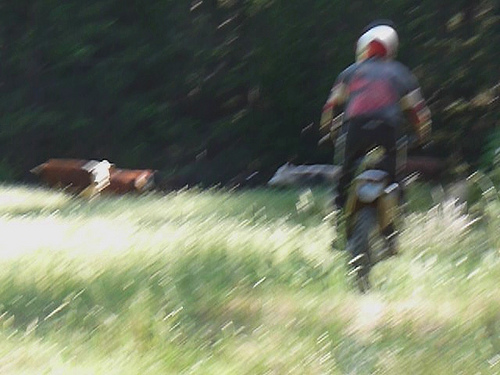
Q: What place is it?
A: It is a field.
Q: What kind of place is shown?
A: It is a field.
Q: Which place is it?
A: It is a field.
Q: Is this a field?
A: Yes, it is a field.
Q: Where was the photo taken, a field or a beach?
A: It was taken at a field.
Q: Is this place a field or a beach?
A: It is a field.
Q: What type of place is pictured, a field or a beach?
A: It is a field.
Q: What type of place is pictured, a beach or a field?
A: It is a field.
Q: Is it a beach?
A: No, it is a field.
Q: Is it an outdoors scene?
A: Yes, it is outdoors.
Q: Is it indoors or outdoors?
A: It is outdoors.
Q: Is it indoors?
A: No, it is outdoors.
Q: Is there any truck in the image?
A: Yes, there is a truck.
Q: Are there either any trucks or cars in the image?
A: Yes, there is a truck.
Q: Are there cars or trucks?
A: Yes, there is a truck.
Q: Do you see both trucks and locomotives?
A: No, there is a truck but no locomotives.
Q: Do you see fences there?
A: No, there are no fences.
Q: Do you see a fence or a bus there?
A: No, there are no fences or buses.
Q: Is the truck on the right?
A: No, the truck is on the left of the image.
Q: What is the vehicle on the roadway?
A: The vehicle is a truck.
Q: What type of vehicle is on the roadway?
A: The vehicle is a truck.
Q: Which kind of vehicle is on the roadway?
A: The vehicle is a truck.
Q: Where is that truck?
A: The truck is on the roadway.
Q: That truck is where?
A: The truck is on the roadway.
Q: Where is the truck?
A: The truck is on the roadway.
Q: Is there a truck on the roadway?
A: Yes, there is a truck on the roadway.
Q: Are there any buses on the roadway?
A: No, there is a truck on the roadway.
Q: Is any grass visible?
A: Yes, there is grass.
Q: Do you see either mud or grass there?
A: Yes, there is grass.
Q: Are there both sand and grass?
A: No, there is grass but no sand.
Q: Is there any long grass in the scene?
A: Yes, there is long grass.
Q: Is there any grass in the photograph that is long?
A: Yes, there is grass that is long.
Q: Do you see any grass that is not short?
A: Yes, there is long grass.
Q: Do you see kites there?
A: No, there are no kites.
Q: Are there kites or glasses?
A: No, there are no kites or glasses.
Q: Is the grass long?
A: Yes, the grass is long.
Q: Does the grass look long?
A: Yes, the grass is long.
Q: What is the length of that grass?
A: The grass is long.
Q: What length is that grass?
A: The grass is long.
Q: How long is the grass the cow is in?
A: The grass is long.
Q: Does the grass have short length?
A: No, the grass is long.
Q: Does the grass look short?
A: No, the grass is long.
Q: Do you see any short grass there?
A: No, there is grass but it is long.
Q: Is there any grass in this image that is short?
A: No, there is grass but it is long.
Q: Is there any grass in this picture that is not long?
A: No, there is grass but it is long.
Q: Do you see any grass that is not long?
A: No, there is grass but it is long.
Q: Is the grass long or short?
A: The grass is long.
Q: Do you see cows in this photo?
A: Yes, there is a cow.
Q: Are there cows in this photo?
A: Yes, there is a cow.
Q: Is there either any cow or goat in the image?
A: Yes, there is a cow.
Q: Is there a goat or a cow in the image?
A: Yes, there is a cow.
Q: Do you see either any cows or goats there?
A: Yes, there is a cow.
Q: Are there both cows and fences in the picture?
A: No, there is a cow but no fences.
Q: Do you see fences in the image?
A: No, there are no fences.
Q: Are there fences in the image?
A: No, there are no fences.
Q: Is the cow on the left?
A: Yes, the cow is on the left of the image.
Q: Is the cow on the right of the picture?
A: No, the cow is on the left of the image.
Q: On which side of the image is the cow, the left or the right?
A: The cow is on the left of the image.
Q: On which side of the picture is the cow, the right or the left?
A: The cow is on the left of the image.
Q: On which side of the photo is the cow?
A: The cow is on the left of the image.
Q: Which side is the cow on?
A: The cow is on the left of the image.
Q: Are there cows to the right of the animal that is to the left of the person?
A: No, the cow is to the left of the animal.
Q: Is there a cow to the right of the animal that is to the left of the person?
A: No, the cow is to the left of the animal.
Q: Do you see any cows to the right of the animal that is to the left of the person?
A: No, the cow is to the left of the animal.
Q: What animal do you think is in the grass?
A: The animal is a cow.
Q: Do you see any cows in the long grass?
A: Yes, there is a cow in the grass.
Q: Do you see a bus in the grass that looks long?
A: No, there is a cow in the grass.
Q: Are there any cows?
A: Yes, there is a cow.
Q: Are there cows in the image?
A: Yes, there is a cow.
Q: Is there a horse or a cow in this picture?
A: Yes, there is a cow.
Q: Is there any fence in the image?
A: No, there are no fences.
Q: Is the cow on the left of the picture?
A: Yes, the cow is on the left of the image.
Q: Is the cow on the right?
A: No, the cow is on the left of the image.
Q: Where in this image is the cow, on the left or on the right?
A: The cow is on the left of the image.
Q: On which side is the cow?
A: The cow is on the left of the image.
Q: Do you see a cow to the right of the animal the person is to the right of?
A: No, the cow is to the left of the animal.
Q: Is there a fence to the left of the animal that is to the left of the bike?
A: No, there is a cow to the left of the animal.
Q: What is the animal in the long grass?
A: The animal is a cow.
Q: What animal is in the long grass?
A: The animal is a cow.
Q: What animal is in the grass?
A: The animal is a cow.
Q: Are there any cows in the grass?
A: Yes, there is a cow in the grass.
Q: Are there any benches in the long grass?
A: No, there is a cow in the grass.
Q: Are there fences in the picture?
A: No, there are no fences.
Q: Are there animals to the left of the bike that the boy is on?
A: Yes, there is an animal to the left of the bike.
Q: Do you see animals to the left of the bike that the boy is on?
A: Yes, there is an animal to the left of the bike.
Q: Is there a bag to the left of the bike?
A: No, there is an animal to the left of the bike.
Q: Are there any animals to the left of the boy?
A: Yes, there is an animal to the left of the boy.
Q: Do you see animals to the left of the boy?
A: Yes, there is an animal to the left of the boy.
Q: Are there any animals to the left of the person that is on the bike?
A: Yes, there is an animal to the left of the boy.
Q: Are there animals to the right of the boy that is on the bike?
A: No, the animal is to the left of the boy.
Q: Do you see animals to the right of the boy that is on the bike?
A: No, the animal is to the left of the boy.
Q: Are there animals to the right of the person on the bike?
A: No, the animal is to the left of the boy.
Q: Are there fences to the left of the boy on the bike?
A: No, there is an animal to the left of the boy.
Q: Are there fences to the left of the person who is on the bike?
A: No, there is an animal to the left of the boy.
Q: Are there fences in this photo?
A: No, there are no fences.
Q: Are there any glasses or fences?
A: No, there are no fences or glasses.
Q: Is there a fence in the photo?
A: No, there are no fences.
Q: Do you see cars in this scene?
A: No, there are no cars.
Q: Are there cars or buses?
A: No, there are no cars or buses.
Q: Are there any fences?
A: No, there are no fences.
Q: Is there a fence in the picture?
A: No, there are no fences.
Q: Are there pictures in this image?
A: No, there are no pictures.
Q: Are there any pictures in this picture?
A: No, there are no pictures.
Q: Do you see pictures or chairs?
A: No, there are no pictures or chairs.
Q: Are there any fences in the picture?
A: No, there are no fences.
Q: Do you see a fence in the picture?
A: No, there are no fences.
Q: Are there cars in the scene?
A: No, there are no cars.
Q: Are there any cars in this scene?
A: No, there are no cars.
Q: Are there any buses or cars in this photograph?
A: No, there are no cars or buses.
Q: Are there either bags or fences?
A: No, there are no fences or bags.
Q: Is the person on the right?
A: Yes, the person is on the right of the image.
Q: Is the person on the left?
A: No, the person is on the right of the image.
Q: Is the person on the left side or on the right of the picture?
A: The person is on the right of the image.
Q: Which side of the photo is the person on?
A: The person is on the right of the image.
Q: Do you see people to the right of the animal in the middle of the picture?
A: Yes, there is a person to the right of the animal.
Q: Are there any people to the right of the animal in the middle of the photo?
A: Yes, there is a person to the right of the animal.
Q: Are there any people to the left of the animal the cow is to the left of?
A: No, the person is to the right of the animal.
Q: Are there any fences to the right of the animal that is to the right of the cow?
A: No, there is a person to the right of the animal.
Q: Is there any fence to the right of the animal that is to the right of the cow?
A: No, there is a person to the right of the animal.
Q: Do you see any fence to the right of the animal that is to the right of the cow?
A: No, there is a person to the right of the animal.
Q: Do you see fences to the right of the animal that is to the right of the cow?
A: No, there is a person to the right of the animal.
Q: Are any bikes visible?
A: Yes, there is a bike.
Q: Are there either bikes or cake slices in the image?
A: Yes, there is a bike.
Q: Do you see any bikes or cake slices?
A: Yes, there is a bike.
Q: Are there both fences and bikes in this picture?
A: No, there is a bike but no fences.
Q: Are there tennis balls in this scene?
A: No, there are no tennis balls.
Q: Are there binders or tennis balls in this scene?
A: No, there are no tennis balls or binders.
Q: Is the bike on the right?
A: Yes, the bike is on the right of the image.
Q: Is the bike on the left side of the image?
A: No, the bike is on the right of the image.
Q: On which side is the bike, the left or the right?
A: The bike is on the right of the image.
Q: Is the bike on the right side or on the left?
A: The bike is on the right of the image.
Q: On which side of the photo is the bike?
A: The bike is on the right of the image.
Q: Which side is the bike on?
A: The bike is on the right of the image.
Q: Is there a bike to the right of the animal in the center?
A: Yes, there is a bike to the right of the animal.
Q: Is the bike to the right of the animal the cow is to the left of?
A: Yes, the bike is to the right of the animal.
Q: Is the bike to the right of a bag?
A: No, the bike is to the right of the animal.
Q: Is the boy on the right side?
A: Yes, the boy is on the right of the image.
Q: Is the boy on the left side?
A: No, the boy is on the right of the image.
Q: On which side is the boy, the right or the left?
A: The boy is on the right of the image.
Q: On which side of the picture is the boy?
A: The boy is on the right of the image.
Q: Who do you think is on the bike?
A: The boy is on the bike.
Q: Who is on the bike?
A: The boy is on the bike.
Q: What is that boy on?
A: The boy is on the bike.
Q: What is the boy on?
A: The boy is on the bike.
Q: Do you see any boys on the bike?
A: Yes, there is a boy on the bike.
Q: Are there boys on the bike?
A: Yes, there is a boy on the bike.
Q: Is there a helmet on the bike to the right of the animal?
A: No, there is a boy on the bike.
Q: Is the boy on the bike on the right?
A: Yes, the boy is on the bike.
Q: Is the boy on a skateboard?
A: No, the boy is on the bike.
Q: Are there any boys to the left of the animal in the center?
A: No, the boy is to the right of the animal.